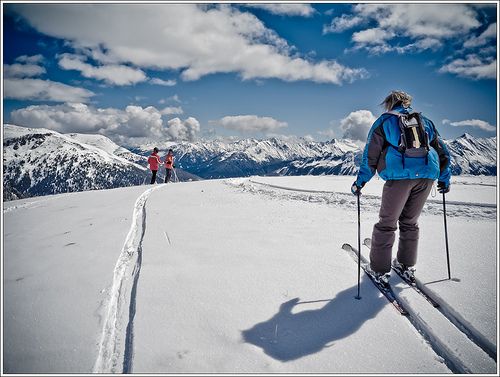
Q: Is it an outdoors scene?
A: Yes, it is outdoors.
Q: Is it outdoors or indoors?
A: It is outdoors.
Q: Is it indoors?
A: No, it is outdoors.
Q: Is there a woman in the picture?
A: Yes, there is a woman.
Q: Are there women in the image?
A: Yes, there is a woman.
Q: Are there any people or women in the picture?
A: Yes, there is a woman.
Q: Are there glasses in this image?
A: No, there are no glasses.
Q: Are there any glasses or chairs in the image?
A: No, there are no glasses or chairs.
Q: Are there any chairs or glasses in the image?
A: No, there are no glasses or chairs.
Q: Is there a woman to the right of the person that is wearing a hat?
A: Yes, there is a woman to the right of the person.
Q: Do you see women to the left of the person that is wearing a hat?
A: No, the woman is to the right of the person.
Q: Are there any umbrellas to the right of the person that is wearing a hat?
A: No, there is a woman to the right of the person.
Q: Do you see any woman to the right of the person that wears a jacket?
A: Yes, there is a woman to the right of the person.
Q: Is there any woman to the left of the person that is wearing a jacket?
A: No, the woman is to the right of the person.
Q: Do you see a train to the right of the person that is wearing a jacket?
A: No, there is a woman to the right of the person.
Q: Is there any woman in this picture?
A: Yes, there is a woman.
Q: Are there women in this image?
A: Yes, there is a woman.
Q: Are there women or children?
A: Yes, there is a woman.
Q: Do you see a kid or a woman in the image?
A: Yes, there is a woman.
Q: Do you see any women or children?
A: Yes, there is a woman.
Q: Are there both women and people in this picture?
A: Yes, there are both a woman and people.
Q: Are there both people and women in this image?
A: Yes, there are both a woman and people.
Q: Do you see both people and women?
A: Yes, there are both a woman and people.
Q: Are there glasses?
A: No, there are no glasses.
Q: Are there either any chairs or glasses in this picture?
A: No, there are no glasses or chairs.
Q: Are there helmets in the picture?
A: No, there are no helmets.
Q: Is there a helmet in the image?
A: No, there are no helmets.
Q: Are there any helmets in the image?
A: No, there are no helmets.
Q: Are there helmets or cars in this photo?
A: No, there are no helmets or cars.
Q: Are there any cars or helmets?
A: No, there are no helmets or cars.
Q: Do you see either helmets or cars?
A: No, there are no helmets or cars.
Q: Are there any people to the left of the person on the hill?
A: Yes, there is a person to the left of the skier.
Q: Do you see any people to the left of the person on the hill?
A: Yes, there is a person to the left of the skier.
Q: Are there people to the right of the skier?
A: No, the person is to the left of the skier.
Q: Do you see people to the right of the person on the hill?
A: No, the person is to the left of the skier.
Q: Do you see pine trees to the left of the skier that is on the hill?
A: No, there is a person to the left of the skier.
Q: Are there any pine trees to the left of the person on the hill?
A: No, there is a person to the left of the skier.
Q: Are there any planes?
A: No, there are no planes.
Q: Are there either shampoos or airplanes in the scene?
A: No, there are no airplanes or shampoos.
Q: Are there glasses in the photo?
A: No, there are no glasses.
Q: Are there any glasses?
A: No, there are no glasses.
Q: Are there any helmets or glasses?
A: No, there are no glasses or helmets.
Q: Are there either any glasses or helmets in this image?
A: No, there are no glasses or helmets.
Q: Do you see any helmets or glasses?
A: No, there are no glasses or helmets.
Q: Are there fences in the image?
A: No, there are no fences.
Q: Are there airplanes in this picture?
A: No, there are no airplanes.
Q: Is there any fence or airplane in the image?
A: No, there are no airplanes or fences.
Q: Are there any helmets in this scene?
A: No, there are no helmets.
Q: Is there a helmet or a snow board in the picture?
A: No, there are no helmets or snowboards.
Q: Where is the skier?
A: The skier is on the hill.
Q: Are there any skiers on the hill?
A: Yes, there is a skier on the hill.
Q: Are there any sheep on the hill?
A: No, there is a skier on the hill.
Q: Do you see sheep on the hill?
A: No, there is a skier on the hill.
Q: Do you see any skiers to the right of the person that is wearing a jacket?
A: Yes, there is a skier to the right of the person.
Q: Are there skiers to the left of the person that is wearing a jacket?
A: No, the skier is to the right of the person.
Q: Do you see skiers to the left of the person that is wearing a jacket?
A: No, the skier is to the right of the person.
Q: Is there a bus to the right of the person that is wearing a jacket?
A: No, there is a skier to the right of the person.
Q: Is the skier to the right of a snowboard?
A: No, the skier is to the right of a person.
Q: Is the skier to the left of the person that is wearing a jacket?
A: No, the skier is to the right of the person.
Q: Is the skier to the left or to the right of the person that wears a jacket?
A: The skier is to the right of the person.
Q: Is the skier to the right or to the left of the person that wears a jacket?
A: The skier is to the right of the person.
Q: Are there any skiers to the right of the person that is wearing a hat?
A: Yes, there is a skier to the right of the person.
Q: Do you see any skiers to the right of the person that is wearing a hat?
A: Yes, there is a skier to the right of the person.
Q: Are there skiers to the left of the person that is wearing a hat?
A: No, the skier is to the right of the person.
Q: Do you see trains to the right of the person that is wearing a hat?
A: No, there is a skier to the right of the person.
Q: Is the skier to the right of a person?
A: Yes, the skier is to the right of a person.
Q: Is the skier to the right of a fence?
A: No, the skier is to the right of a person.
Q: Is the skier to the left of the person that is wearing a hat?
A: No, the skier is to the right of the person.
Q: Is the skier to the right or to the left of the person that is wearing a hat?
A: The skier is to the right of the person.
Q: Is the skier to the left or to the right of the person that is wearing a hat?
A: The skier is to the right of the person.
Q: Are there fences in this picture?
A: No, there are no fences.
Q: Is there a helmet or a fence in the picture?
A: No, there are no fences or helmets.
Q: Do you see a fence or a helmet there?
A: No, there are no fences or helmets.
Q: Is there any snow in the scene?
A: Yes, there is snow.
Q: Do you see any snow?
A: Yes, there is snow.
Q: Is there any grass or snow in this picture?
A: Yes, there is snow.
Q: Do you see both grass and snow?
A: No, there is snow but no grass.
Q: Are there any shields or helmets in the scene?
A: No, there are no helmets or shields.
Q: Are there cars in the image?
A: No, there are no cars.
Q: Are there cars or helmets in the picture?
A: No, there are no cars or helmets.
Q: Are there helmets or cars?
A: No, there are no cars or helmets.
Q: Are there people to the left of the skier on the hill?
A: Yes, there is a person to the left of the skier.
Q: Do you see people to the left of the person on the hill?
A: Yes, there is a person to the left of the skier.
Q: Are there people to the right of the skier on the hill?
A: No, the person is to the left of the skier.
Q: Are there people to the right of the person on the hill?
A: No, the person is to the left of the skier.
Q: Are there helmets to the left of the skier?
A: No, there is a person to the left of the skier.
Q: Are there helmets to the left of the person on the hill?
A: No, there is a person to the left of the skier.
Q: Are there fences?
A: No, there are no fences.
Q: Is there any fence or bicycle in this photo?
A: No, there are no fences or bicycles.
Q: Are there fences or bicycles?
A: No, there are no fences or bicycles.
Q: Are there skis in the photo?
A: Yes, there are skis.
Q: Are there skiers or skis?
A: Yes, there are skis.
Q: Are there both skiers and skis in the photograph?
A: Yes, there are both skis and a skier.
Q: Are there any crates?
A: No, there are no crates.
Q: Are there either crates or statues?
A: No, there are no crates or statues.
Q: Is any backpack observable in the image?
A: Yes, there is a backpack.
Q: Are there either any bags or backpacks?
A: Yes, there is a backpack.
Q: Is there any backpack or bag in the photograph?
A: Yes, there is a backpack.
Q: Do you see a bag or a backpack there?
A: Yes, there is a backpack.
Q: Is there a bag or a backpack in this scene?
A: Yes, there is a backpack.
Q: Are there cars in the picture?
A: No, there are no cars.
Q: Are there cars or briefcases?
A: No, there are no cars or briefcases.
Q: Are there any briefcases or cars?
A: No, there are no cars or briefcases.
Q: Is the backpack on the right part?
A: Yes, the backpack is on the right of the image.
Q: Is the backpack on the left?
A: No, the backpack is on the right of the image.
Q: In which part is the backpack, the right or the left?
A: The backpack is on the right of the image.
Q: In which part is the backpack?
A: The backpack is on the right of the image.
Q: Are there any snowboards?
A: No, there are no snowboards.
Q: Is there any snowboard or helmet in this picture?
A: No, there are no snowboards or helmets.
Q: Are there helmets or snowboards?
A: No, there are no snowboards or helmets.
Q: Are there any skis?
A: Yes, there are skis.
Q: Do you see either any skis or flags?
A: Yes, there are skis.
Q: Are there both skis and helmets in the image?
A: No, there are skis but no helmets.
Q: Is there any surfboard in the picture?
A: No, there are no surfboards.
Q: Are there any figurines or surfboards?
A: No, there are no surfboards or figurines.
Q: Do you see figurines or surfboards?
A: No, there are no surfboards or figurines.